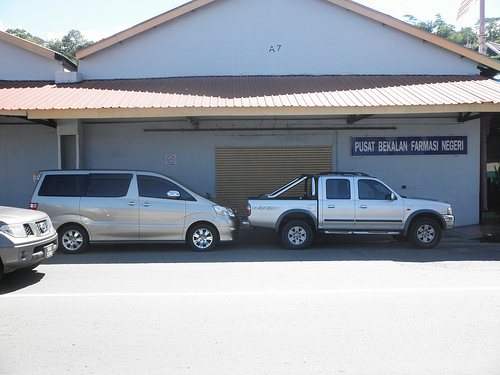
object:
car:
[27, 168, 238, 255]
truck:
[246, 172, 455, 250]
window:
[356, 179, 398, 201]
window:
[318, 174, 357, 203]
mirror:
[389, 191, 396, 200]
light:
[447, 207, 453, 215]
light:
[247, 204, 253, 216]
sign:
[350, 135, 468, 157]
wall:
[0, 126, 485, 229]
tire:
[409, 215, 443, 250]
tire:
[280, 219, 314, 250]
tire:
[187, 221, 218, 252]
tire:
[57, 223, 89, 254]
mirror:
[167, 190, 182, 200]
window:
[136, 174, 196, 201]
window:
[37, 172, 133, 197]